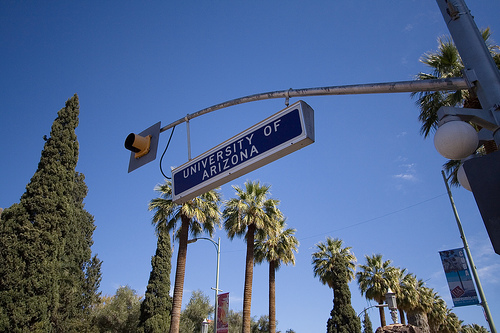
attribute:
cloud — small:
[361, 143, 420, 187]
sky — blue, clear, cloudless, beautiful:
[144, 66, 438, 205]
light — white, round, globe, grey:
[426, 104, 490, 169]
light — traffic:
[113, 121, 171, 180]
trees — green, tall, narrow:
[172, 201, 443, 321]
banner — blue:
[428, 244, 481, 310]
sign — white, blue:
[162, 130, 324, 189]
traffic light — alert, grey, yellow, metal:
[104, 108, 191, 175]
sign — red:
[209, 286, 234, 329]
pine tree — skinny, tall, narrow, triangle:
[141, 206, 179, 324]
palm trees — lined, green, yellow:
[174, 191, 263, 329]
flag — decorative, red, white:
[215, 288, 237, 324]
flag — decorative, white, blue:
[430, 240, 493, 318]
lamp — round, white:
[433, 118, 478, 165]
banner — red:
[199, 278, 249, 332]